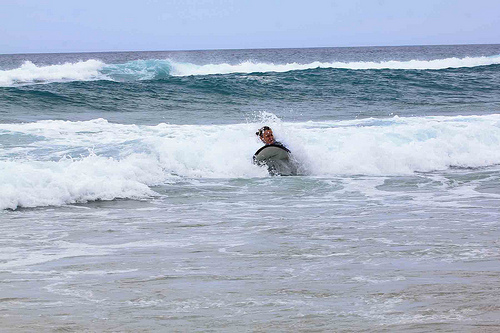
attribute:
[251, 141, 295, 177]
surfboard — white, black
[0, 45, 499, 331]
water — blue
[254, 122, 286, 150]
man — flinching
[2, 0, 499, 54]
sky — clear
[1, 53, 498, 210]
waves — white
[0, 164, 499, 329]
water — clear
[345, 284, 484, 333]
water — clear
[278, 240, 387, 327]
water — clear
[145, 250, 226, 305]
water — clear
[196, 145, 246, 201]
wave — forming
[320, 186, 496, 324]
water — calm 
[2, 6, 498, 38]
sky — blue 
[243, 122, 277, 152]
man — riding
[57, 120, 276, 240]
water — splashing 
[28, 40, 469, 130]
waves — crashing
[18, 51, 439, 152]
ocean — choppy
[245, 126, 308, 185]
person — wet, brown haired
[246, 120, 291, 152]
eyes — closed